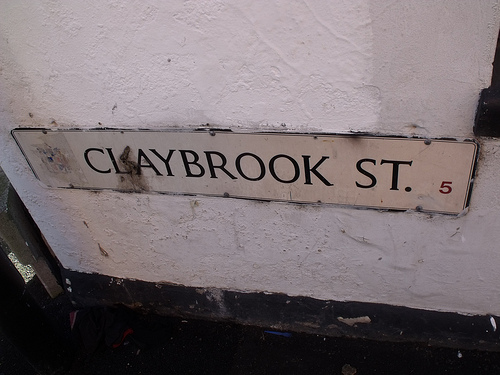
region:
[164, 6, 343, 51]
white stucco on a wall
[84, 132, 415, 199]
black letters on a sign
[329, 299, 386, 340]
peeling paint on the edge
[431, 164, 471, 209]
a red number on the sign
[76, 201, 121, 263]
dirt specks on the wall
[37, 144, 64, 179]
a square hole in the sign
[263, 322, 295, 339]
a blue smudge on the bottom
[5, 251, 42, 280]
a metal latch on the side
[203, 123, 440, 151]
metal screws in the sign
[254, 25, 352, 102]
a rough pattern in the stucco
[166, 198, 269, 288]
this is the wall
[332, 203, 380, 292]
the wall is white in color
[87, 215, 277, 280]
the wall is made of stone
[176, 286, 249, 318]
the wall has a black strip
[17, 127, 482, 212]
this is a signpost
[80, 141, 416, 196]
the signpost has writings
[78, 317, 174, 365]
this is the floorthe floor is black in color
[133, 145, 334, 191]
the writings are written in bold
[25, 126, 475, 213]
the signpost is rectangular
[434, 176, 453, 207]
the number is red in color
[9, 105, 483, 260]
A square white sign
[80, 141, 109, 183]
A black letter "C"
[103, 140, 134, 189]
A black letter "L"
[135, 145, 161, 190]
A black letter "A"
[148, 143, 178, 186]
A black letter "Y"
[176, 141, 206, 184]
A black letter "B"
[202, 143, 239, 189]
A black letter "R"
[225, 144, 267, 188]
A black letter "O"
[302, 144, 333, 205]
A black letter "K"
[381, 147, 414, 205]
A black letter "T"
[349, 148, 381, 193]
A black letter "S"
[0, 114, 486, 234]
Sign is white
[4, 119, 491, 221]
Sign has black words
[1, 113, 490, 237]
Sign has black border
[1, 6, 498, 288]
Sign is on a white wall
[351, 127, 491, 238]
Sign has a number 5 on right side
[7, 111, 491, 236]
Sign letters says "Claybrook St"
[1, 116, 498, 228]
Sign is old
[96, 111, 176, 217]
Sign has black spots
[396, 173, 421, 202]
A point on sign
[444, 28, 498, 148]
White wall is black on right side